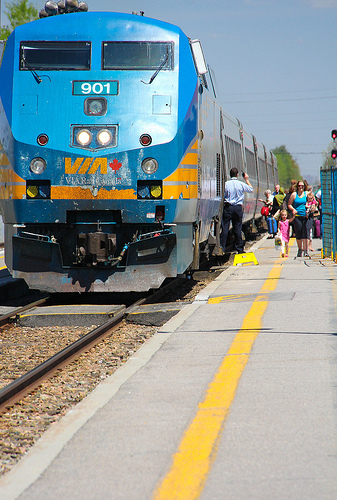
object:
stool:
[233, 251, 258, 268]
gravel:
[0, 322, 160, 467]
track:
[1, 291, 152, 408]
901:
[81, 82, 110, 96]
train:
[2, 13, 278, 294]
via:
[63, 155, 109, 178]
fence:
[319, 166, 336, 263]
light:
[330, 129, 336, 135]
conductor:
[217, 168, 255, 252]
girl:
[276, 210, 298, 260]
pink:
[280, 222, 290, 236]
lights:
[331, 148, 336, 163]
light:
[75, 127, 93, 148]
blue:
[222, 178, 240, 201]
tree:
[274, 149, 297, 183]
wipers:
[19, 57, 42, 86]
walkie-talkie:
[239, 169, 249, 180]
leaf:
[109, 160, 123, 176]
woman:
[289, 181, 313, 258]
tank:
[291, 190, 307, 217]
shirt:
[225, 178, 256, 209]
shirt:
[276, 219, 292, 244]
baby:
[304, 196, 318, 215]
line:
[155, 256, 286, 498]